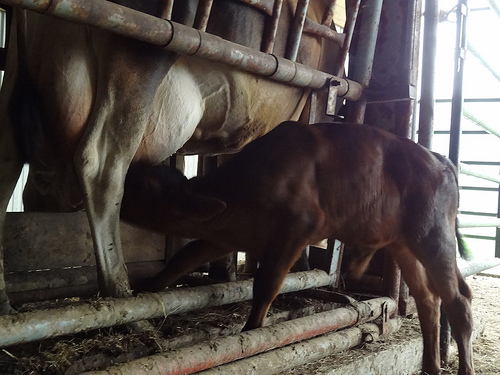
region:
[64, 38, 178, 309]
hind leg of a cow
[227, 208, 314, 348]
front leg of a cow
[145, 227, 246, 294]
front leg of a calf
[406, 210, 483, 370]
hind leg of a calf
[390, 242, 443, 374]
hind leg of a calf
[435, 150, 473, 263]
tail of a calf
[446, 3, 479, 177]
brown metal pole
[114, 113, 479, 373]
a brown colored calf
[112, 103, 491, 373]
a brown calf drinking milk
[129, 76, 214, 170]
udder on a cow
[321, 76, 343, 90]
A nut and bolt.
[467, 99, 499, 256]
A fence out side.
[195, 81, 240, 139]
Veins on the cow.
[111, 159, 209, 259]
The calf drinking milk.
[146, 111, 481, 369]
A small brown calf.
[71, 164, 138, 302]
The leg is filthy.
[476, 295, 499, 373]
Hay on the ground.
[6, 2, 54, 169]
Tail of the cow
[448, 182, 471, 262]
tal of the calf.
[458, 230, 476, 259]
the tail is green.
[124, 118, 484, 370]
calf drinking mothers milk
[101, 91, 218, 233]
cow is full of milk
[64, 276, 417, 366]
pipes on the ground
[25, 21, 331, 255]
cow is tan and white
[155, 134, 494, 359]
calf is dark brown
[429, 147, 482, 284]
calf has short tail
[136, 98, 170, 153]
veins in cows udders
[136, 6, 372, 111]
cow in metal enclosure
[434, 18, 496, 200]
outside there is a lot of light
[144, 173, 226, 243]
calf's ears are pointed back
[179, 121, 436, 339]
A cow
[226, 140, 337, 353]
A cow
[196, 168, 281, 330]
A cow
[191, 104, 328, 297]
A cow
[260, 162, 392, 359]
A cow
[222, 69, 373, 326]
A cow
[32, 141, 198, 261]
baby cow nursing from mom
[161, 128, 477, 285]
brown baby cow with mom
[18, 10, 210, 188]
big white mom cow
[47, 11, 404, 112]
steel cage around cow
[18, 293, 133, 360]
hay below cow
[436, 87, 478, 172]
metal fence outside of housing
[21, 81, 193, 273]
brown baby cow eating from mother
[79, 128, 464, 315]
brown baby cow trying to reach mom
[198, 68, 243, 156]
veins on the cow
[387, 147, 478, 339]
muscles on a baby cow